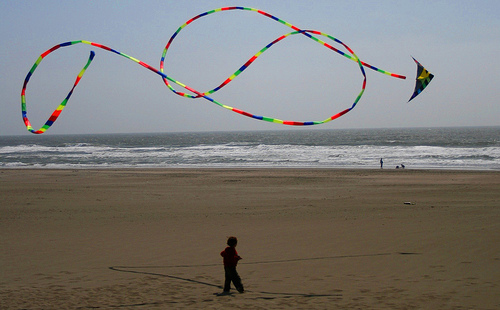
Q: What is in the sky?
A: Rainbow tailed kite.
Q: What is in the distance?
A: The ocean.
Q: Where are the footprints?
A: In sand.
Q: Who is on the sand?
A: Little boy.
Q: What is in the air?
A: Kite.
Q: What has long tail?
A: Colorful kite.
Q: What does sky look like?
A: Clear and blue.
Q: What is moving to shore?
A: Waves.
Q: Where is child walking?
A: On the sand.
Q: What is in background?
A: Water.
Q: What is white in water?
A: White caps.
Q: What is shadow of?
A: Kite.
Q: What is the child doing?
A: Flying a kite.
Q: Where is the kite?
A: Flying in the air.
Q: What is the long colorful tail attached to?
A: A kite.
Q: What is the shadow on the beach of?
A: The kite.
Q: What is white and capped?
A: Ocean waves.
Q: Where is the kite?
A: Flying in the sky.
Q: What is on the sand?
A: Kite's shadow.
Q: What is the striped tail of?
A: Kite.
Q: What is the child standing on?
A: Sand.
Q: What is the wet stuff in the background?
A: The ocean.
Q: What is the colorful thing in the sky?
A: A kite.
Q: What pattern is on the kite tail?
A: Rainbow stripes.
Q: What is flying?
A: Kite.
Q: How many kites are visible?
A: One.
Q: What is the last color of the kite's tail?
A: Blue.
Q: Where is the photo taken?
A: Beach.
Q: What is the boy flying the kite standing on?
A: Sand.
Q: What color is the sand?
A: Tan.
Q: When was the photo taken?
A: Daytime.